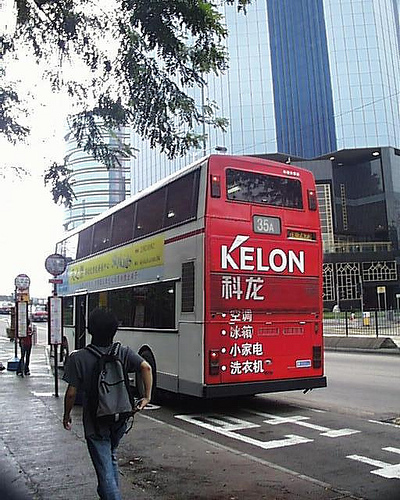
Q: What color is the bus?
A: Red and white.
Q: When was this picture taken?
A: Daytime.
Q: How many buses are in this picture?
A: One.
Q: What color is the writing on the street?
A: White.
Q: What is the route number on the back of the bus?
A: 35a.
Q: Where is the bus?
A: On the street.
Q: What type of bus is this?
A: Double decker.